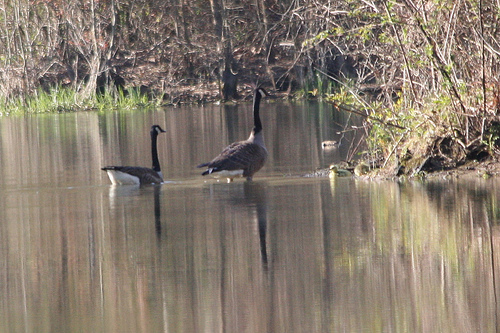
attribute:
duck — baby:
[325, 160, 356, 182]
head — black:
[148, 119, 168, 146]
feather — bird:
[198, 148, 233, 179]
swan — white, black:
[95, 120, 170, 189]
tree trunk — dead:
[216, 51, 245, 106]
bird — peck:
[133, 117, 179, 183]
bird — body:
[196, 85, 271, 183]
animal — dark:
[101, 120, 175, 188]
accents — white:
[108, 169, 140, 189]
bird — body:
[193, 55, 295, 214]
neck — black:
[238, 104, 284, 155]